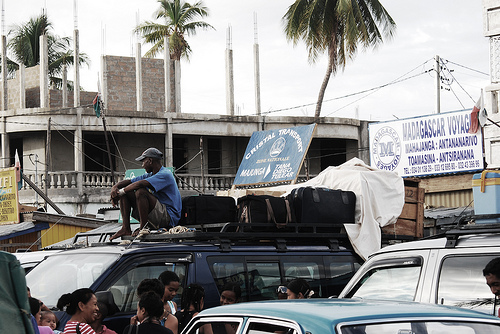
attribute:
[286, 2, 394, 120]
palm tree — green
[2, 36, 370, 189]
building — gray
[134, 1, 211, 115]
palm tree — green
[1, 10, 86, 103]
palm tree — green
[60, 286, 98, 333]
people — smiling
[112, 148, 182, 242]
man — african-american, black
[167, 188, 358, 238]
luggage — black, large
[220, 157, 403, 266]
sheet — white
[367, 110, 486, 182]
board — white, blue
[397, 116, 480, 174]
letters — blue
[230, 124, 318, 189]
board — blue, white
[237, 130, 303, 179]
letters — white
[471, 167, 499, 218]
trunk — blue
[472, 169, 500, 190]
edges — brown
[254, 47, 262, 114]
pole — gray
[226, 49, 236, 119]
pole — gray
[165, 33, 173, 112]
pole — gray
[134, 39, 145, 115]
pole — gray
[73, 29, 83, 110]
pole — gray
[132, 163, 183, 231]
shirt — blue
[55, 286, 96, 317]
hair — black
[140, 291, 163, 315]
hair — black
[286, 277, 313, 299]
hair — black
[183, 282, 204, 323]
hair — black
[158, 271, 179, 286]
hair — black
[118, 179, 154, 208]
knees — up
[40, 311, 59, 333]
child — small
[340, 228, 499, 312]
car — white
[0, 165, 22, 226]
sign — yellow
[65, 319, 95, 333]
shirt — white, red